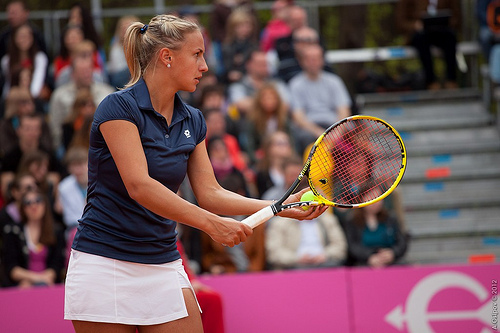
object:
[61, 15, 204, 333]
people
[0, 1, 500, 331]
stands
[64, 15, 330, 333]
woman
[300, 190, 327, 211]
ball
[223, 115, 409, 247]
racket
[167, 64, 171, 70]
earring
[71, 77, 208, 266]
shirt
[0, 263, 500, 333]
wall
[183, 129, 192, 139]
logo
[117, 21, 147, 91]
ponytail